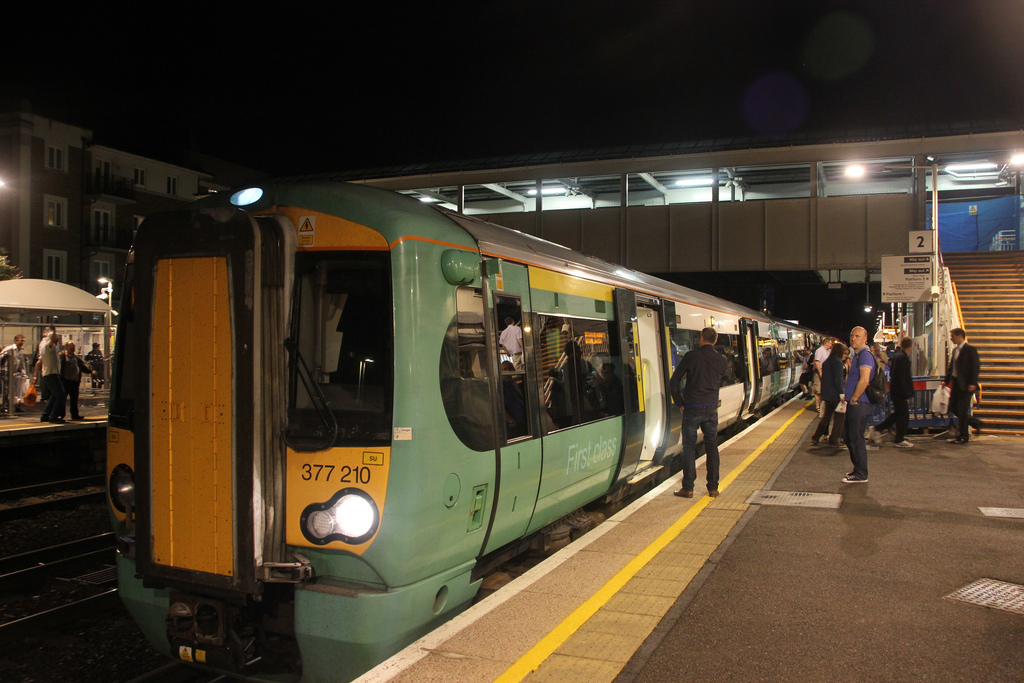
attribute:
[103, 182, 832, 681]
train — green, yellow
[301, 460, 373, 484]
numbers — black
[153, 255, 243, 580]
door — yellow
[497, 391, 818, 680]
line — yellow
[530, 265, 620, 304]
line — yellow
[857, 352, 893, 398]
backpack — black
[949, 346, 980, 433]
suit — black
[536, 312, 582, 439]
window — black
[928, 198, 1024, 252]
wall — blue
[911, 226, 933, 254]
sign — white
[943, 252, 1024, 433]
stairway — yellow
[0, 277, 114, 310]
canopy — white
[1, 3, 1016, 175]
sky — black